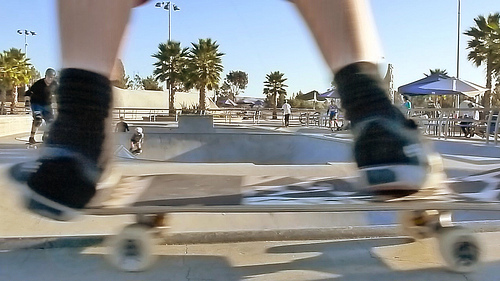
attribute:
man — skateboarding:
[23, 67, 60, 142]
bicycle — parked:
[298, 106, 326, 128]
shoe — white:
[353, 111, 456, 193]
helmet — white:
[133, 122, 145, 132]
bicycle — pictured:
[295, 105, 330, 133]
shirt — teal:
[403, 101, 410, 111]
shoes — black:
[349, 117, 431, 191]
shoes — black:
[17, 145, 96, 222]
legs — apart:
[36, 0, 449, 201]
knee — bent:
[34, 116, 43, 126]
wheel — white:
[95, 222, 167, 272]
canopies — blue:
[398, 75, 485, 96]